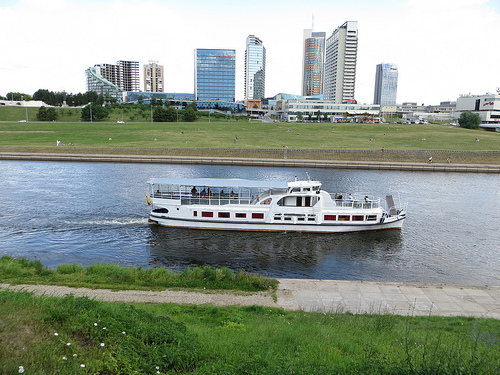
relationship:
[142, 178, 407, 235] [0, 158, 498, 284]
boat on river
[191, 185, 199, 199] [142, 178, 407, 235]
person on boat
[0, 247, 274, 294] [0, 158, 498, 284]
grass by river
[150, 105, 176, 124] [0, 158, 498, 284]
tree behind river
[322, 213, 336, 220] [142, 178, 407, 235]
window on boat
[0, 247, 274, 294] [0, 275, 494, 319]
grass by sidewalk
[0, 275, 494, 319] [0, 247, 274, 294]
sidewalk by grass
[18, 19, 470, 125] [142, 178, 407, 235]
city behind boat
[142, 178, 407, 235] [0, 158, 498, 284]
boat in river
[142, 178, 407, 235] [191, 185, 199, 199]
boat with a person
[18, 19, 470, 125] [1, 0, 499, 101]
city in sky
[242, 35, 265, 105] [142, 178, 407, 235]
buidling behind boat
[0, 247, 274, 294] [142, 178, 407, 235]
grass in front of boat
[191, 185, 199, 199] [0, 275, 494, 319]
person on sidewalk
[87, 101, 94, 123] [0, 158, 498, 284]
post by river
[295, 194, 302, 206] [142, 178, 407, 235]
door on boat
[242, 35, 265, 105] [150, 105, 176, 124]
buidling behind tree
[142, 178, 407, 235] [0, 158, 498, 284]
boat down river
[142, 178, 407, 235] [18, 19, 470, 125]
boat in city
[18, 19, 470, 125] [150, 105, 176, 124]
city behind tree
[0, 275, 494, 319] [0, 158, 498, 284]
sidewalk along river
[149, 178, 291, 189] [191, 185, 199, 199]
canopy over person